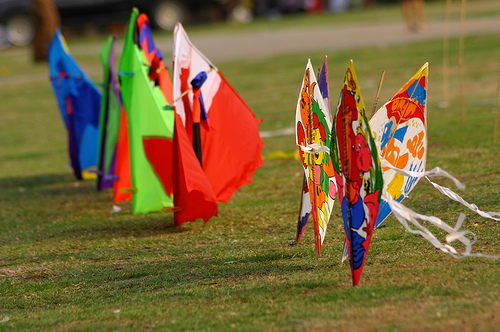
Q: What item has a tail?
A: A kite.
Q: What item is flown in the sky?
A: A kite.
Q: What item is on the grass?
A: A kite.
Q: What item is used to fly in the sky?
A: A kite.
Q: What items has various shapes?
A: A kite.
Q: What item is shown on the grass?
A: A shadow.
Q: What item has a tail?
A: A kite.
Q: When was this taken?
A: Daylight hours.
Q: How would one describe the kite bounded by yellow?
A: KITE IS GREEN AND RED.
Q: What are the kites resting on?
A: Grass.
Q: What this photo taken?
A: Outdoors.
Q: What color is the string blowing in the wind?
A: White.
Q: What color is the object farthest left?
A: Blue.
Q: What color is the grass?
A: Brown and green.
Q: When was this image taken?
A: Daytime.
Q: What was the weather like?
A: Windy.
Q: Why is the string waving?
A: It's windy outside.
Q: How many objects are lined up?
A: 9.